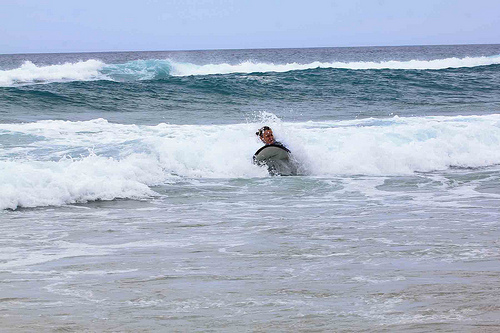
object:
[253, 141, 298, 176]
surfboard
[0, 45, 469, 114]
water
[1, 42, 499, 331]
ocean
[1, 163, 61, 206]
waves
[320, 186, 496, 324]
water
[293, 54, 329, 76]
waves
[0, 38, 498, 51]
horizon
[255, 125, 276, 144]
head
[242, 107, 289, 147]
man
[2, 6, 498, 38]
sky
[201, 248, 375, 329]
water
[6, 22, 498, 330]
shore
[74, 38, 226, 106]
wave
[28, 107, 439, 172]
wave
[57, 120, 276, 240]
water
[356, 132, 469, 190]
waves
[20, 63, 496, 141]
swell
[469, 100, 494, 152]
waves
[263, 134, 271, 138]
eyes